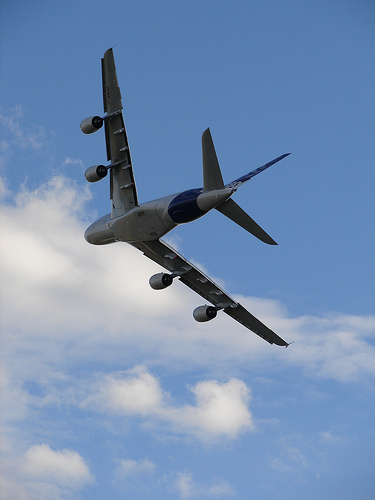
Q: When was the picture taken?
A: Daytime.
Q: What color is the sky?
A: Blue.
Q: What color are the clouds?
A: White.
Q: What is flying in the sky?
A: A plane.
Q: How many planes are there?
A: One.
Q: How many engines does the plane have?
A: Four.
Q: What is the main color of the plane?
A: White.